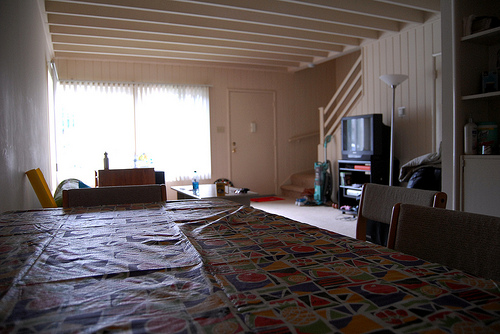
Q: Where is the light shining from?
A: Window.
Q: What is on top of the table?
A: Tablecloth.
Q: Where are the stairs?
A: Back right.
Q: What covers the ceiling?
A: Beams/.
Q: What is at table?
A: Wooden chairs.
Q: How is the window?
A: Large sunlit rectangular.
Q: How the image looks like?
A: Good.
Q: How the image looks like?
A: Dull.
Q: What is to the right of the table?
A: Two grey and brown chairs.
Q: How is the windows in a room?
A: Large.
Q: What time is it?
A: Daytime.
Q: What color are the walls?
A: White.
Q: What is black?
A: The television.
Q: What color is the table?
A: Multi colored.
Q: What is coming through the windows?
A: Light.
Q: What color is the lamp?
A: White.